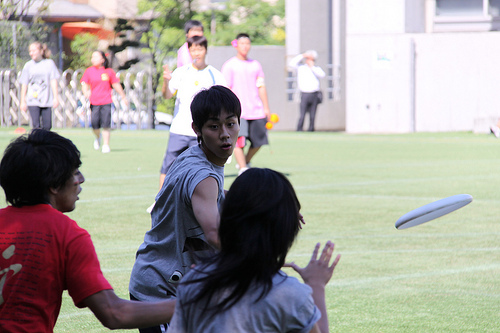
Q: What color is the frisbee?
A: White.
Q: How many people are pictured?
A: 9.